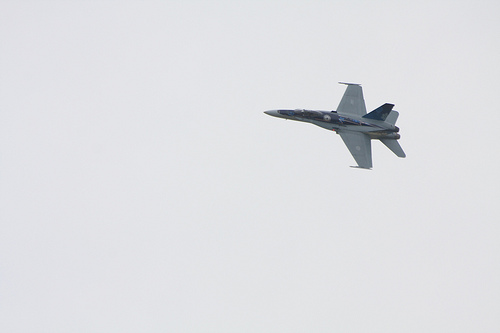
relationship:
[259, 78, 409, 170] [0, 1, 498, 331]
aircraft in sky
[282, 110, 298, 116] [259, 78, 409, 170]
cockpit on aircraft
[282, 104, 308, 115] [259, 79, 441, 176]
cockpit on aircraft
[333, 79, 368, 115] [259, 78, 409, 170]
wing of aircraft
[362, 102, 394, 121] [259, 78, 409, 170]
tail fin on aircraft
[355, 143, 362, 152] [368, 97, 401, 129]
design on wing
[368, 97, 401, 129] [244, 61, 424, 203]
wing on aircraft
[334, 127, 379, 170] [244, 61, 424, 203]
wing on aircraft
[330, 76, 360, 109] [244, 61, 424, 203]
wing on aircraft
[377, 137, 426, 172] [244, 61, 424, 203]
wing on aircraft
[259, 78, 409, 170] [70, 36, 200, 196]
aircraft flying in sky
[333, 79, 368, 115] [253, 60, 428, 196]
wing on aircraft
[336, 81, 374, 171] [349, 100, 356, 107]
wings have logo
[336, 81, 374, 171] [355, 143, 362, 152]
wings have design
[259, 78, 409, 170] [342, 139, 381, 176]
aircraft has wing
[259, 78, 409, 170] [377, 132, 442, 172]
aircraft has wing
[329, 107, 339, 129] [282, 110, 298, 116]
design on cockpit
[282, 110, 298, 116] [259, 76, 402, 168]
cockpit of aircraft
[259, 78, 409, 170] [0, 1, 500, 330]
aircraft in cloudy sky